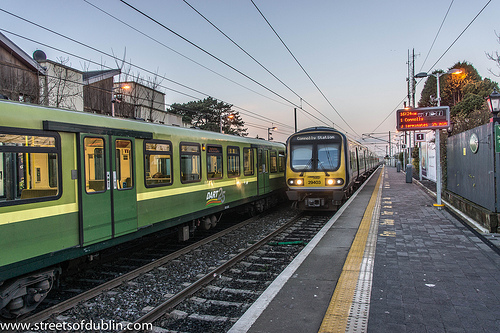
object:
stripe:
[0, 172, 285, 229]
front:
[283, 125, 347, 212]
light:
[413, 69, 462, 79]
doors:
[72, 126, 146, 251]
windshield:
[290, 134, 340, 171]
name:
[203, 187, 225, 209]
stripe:
[332, 170, 385, 331]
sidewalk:
[322, 153, 495, 332]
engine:
[277, 124, 353, 212]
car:
[0, 92, 283, 319]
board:
[395, 104, 452, 131]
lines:
[41, 119, 155, 140]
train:
[0, 95, 288, 319]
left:
[0, 0, 280, 331]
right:
[280, 120, 381, 205]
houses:
[0, 33, 209, 127]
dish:
[33, 48, 47, 62]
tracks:
[24, 198, 331, 333]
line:
[134, 175, 260, 204]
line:
[336, 161, 390, 329]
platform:
[217, 159, 496, 329]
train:
[280, 123, 380, 214]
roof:
[34, 54, 85, 82]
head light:
[323, 175, 344, 188]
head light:
[287, 177, 303, 187]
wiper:
[317, 158, 330, 177]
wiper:
[299, 157, 313, 177]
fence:
[442, 116, 499, 233]